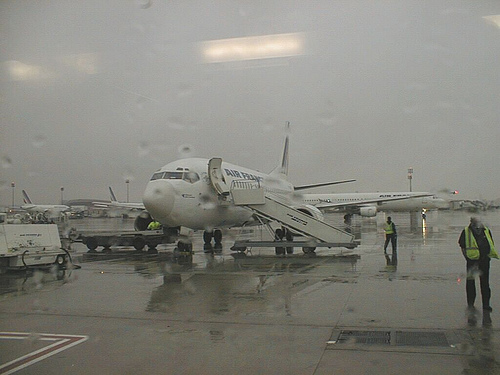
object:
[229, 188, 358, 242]
stairs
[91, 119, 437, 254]
plane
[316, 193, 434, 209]
wing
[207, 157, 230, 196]
door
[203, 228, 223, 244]
landing gear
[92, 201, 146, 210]
wing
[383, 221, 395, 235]
vest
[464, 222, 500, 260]
safety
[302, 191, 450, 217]
airplane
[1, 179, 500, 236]
background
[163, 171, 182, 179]
windows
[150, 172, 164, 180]
window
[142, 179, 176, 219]
nose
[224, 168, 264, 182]
writing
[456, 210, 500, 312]
person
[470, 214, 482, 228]
head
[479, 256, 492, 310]
leg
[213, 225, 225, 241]
wheel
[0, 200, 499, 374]
tarmac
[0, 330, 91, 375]
line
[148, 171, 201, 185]
cockpit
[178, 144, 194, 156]
water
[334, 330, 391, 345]
vent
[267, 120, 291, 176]
tail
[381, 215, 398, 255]
man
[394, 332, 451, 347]
drain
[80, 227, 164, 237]
bed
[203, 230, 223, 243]
tire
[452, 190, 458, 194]
light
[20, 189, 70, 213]
jet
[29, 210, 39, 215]
passengers